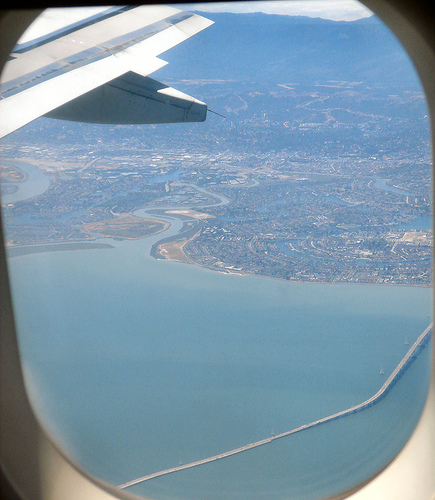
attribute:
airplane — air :
[3, 6, 433, 495]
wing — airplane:
[0, 1, 218, 142]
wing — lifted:
[30, 5, 204, 131]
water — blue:
[42, 281, 411, 438]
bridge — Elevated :
[235, 364, 404, 431]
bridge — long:
[101, 294, 433, 484]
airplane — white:
[4, 8, 227, 147]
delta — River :
[54, 166, 433, 311]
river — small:
[132, 182, 228, 247]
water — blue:
[35, 296, 412, 472]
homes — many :
[242, 157, 402, 278]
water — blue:
[95, 306, 216, 386]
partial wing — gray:
[156, 410, 383, 436]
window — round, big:
[5, 12, 432, 498]